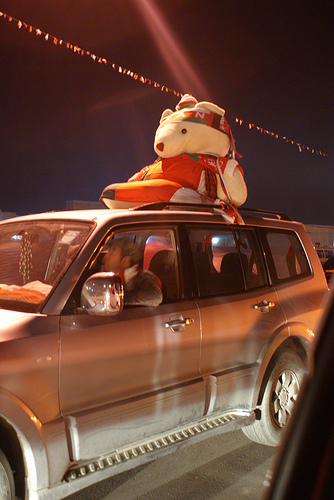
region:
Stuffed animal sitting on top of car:
[98, 94, 249, 209]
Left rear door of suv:
[192, 221, 294, 416]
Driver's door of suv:
[57, 218, 206, 472]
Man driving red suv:
[91, 231, 164, 308]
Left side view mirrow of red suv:
[80, 271, 127, 316]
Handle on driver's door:
[160, 315, 199, 330]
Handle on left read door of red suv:
[253, 299, 275, 312]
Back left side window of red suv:
[261, 223, 318, 290]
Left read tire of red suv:
[239, 345, 308, 445]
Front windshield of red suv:
[3, 217, 98, 308]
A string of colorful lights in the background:
[0, 2, 333, 154]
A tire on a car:
[242, 337, 300, 451]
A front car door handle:
[160, 312, 195, 333]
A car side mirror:
[78, 272, 125, 320]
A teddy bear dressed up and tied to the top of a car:
[96, 93, 247, 214]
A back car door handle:
[251, 297, 277, 314]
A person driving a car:
[94, 233, 159, 307]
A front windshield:
[1, 220, 96, 306]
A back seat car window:
[180, 225, 264, 294]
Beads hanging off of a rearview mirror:
[15, 228, 39, 286]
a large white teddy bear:
[102, 94, 248, 208]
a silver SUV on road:
[2, 211, 329, 495]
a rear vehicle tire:
[241, 348, 304, 445]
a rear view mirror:
[80, 273, 123, 315]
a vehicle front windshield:
[0, 220, 93, 309]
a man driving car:
[97, 234, 163, 308]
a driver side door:
[61, 219, 206, 469]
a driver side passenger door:
[186, 220, 288, 417]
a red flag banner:
[0, 8, 333, 160]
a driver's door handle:
[165, 317, 196, 327]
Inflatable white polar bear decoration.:
[97, 97, 245, 209]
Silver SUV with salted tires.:
[1, 216, 333, 473]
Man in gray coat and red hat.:
[91, 227, 177, 311]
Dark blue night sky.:
[5, 21, 333, 90]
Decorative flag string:
[0, 7, 175, 99]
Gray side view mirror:
[77, 273, 129, 319]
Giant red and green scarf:
[180, 150, 253, 221]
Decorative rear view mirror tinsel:
[11, 210, 48, 298]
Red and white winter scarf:
[121, 248, 160, 289]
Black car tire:
[243, 345, 309, 453]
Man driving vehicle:
[88, 236, 163, 310]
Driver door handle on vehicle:
[165, 314, 193, 331]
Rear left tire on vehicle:
[237, 345, 313, 446]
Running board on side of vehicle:
[66, 411, 235, 480]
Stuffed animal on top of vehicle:
[98, 92, 248, 209]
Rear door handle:
[252, 298, 272, 310]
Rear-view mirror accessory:
[16, 233, 34, 285]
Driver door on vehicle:
[58, 221, 205, 485]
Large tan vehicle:
[0, 201, 332, 498]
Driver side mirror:
[76, 272, 124, 318]